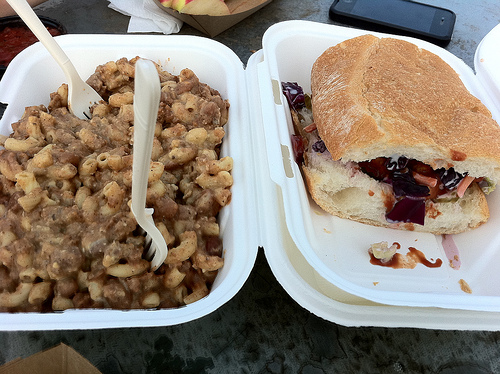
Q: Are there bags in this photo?
A: No, there are no bags.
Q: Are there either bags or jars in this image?
A: No, there are no bags or jars.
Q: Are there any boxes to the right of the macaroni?
A: Yes, there is a box to the right of the macaroni.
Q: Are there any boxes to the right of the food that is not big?
A: Yes, there is a box to the right of the macaroni.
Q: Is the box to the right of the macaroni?
A: Yes, the box is to the right of the macaroni.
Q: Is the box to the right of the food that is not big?
A: Yes, the box is to the right of the macaroni.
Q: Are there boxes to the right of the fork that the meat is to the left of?
A: Yes, there is a box to the right of the fork.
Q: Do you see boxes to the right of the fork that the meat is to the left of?
A: Yes, there is a box to the right of the fork.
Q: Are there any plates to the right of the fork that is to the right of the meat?
A: No, there is a box to the right of the fork.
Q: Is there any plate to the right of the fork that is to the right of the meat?
A: No, there is a box to the right of the fork.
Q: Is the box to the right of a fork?
A: Yes, the box is to the right of a fork.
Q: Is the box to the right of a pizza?
A: No, the box is to the right of a fork.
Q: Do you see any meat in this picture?
A: Yes, there is meat.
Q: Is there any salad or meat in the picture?
A: Yes, there is meat.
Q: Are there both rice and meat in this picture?
A: No, there is meat but no rice.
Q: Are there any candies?
A: No, there are no candies.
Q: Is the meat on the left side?
A: Yes, the meat is on the left of the image.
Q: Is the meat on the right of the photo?
A: No, the meat is on the left of the image.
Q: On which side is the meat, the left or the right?
A: The meat is on the left of the image.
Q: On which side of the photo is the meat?
A: The meat is on the left of the image.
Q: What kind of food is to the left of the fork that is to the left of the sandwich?
A: The food is meat.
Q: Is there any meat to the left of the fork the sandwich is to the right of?
A: Yes, there is meat to the left of the fork.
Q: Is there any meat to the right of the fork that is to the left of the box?
A: No, the meat is to the left of the fork.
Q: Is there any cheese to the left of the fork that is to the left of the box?
A: No, there is meat to the left of the fork.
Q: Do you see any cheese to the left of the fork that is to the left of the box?
A: No, there is meat to the left of the fork.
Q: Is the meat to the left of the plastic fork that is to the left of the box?
A: Yes, the meat is to the left of the fork.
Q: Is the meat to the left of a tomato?
A: No, the meat is to the left of the fork.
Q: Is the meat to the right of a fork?
A: No, the meat is to the left of a fork.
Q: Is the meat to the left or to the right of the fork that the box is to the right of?
A: The meat is to the left of the fork.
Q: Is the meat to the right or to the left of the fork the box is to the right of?
A: The meat is to the left of the fork.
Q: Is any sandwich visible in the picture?
A: Yes, there is a sandwich.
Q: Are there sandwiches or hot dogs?
A: Yes, there is a sandwich.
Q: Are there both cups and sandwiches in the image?
A: No, there is a sandwich but no cups.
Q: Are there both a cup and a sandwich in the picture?
A: No, there is a sandwich but no cups.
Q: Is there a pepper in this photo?
A: No, there are no peppers.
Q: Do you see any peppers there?
A: No, there are no peppers.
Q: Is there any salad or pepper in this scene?
A: No, there are no peppers or salad.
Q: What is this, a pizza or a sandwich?
A: This is a sandwich.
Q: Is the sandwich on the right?
A: Yes, the sandwich is on the right of the image.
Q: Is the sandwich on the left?
A: No, the sandwich is on the right of the image.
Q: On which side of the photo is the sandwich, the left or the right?
A: The sandwich is on the right of the image.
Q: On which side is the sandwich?
A: The sandwich is on the right of the image.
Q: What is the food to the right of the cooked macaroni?
A: The food is a sandwich.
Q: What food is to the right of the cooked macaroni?
A: The food is a sandwich.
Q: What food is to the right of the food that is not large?
A: The food is a sandwich.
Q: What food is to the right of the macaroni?
A: The food is a sandwich.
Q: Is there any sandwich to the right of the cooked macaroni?
A: Yes, there is a sandwich to the right of the macaroni.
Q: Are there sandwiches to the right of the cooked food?
A: Yes, there is a sandwich to the right of the macaroni.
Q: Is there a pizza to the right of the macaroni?
A: No, there is a sandwich to the right of the macaroni.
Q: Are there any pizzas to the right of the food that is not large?
A: No, there is a sandwich to the right of the macaroni.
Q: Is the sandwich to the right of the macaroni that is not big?
A: Yes, the sandwich is to the right of the macaroni.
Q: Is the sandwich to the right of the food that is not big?
A: Yes, the sandwich is to the right of the macaroni.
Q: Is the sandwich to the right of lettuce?
A: No, the sandwich is to the right of the macaroni.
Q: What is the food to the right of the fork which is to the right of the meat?
A: The food is a sandwich.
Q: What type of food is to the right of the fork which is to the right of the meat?
A: The food is a sandwich.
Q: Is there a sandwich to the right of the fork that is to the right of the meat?
A: Yes, there is a sandwich to the right of the fork.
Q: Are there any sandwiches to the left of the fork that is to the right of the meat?
A: No, the sandwich is to the right of the fork.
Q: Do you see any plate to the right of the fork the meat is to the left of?
A: No, there is a sandwich to the right of the fork.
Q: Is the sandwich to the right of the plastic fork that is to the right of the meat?
A: Yes, the sandwich is to the right of the fork.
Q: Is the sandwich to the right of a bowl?
A: No, the sandwich is to the right of the fork.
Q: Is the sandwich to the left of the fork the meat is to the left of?
A: No, the sandwich is to the right of the fork.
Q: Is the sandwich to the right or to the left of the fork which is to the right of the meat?
A: The sandwich is to the right of the fork.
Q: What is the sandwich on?
A: The sandwich is on the sauce.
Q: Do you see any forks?
A: Yes, there is a fork.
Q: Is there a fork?
A: Yes, there is a fork.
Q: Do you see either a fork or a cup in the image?
A: Yes, there is a fork.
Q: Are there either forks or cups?
A: Yes, there is a fork.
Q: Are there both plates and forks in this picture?
A: No, there is a fork but no plates.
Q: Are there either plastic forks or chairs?
A: Yes, there is a plastic fork.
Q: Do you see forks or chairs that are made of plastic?
A: Yes, the fork is made of plastic.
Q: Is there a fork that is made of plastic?
A: Yes, there is a fork that is made of plastic.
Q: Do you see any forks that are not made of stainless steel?
A: Yes, there is a fork that is made of plastic.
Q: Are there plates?
A: No, there are no plates.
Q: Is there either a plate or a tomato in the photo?
A: No, there are no plates or tomatoes.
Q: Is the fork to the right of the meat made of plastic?
A: Yes, the fork is made of plastic.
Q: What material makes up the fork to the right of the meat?
A: The fork is made of plastic.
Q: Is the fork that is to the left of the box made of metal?
A: No, the fork is made of plastic.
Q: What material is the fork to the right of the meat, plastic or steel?
A: The fork is made of plastic.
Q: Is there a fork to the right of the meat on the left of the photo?
A: Yes, there is a fork to the right of the meat.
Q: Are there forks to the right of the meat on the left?
A: Yes, there is a fork to the right of the meat.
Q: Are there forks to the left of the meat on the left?
A: No, the fork is to the right of the meat.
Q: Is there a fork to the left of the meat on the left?
A: No, the fork is to the right of the meat.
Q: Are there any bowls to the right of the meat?
A: No, there is a fork to the right of the meat.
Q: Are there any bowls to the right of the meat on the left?
A: No, there is a fork to the right of the meat.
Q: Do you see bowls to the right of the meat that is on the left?
A: No, there is a fork to the right of the meat.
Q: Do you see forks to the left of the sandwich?
A: Yes, there is a fork to the left of the sandwich.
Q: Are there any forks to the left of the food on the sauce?
A: Yes, there is a fork to the left of the sandwich.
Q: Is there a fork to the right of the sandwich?
A: No, the fork is to the left of the sandwich.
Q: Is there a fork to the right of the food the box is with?
A: No, the fork is to the left of the sandwich.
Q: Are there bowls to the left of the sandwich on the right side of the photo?
A: No, there is a fork to the left of the sandwich.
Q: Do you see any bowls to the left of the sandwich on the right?
A: No, there is a fork to the left of the sandwich.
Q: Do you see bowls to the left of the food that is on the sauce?
A: No, there is a fork to the left of the sandwich.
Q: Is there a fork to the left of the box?
A: Yes, there is a fork to the left of the box.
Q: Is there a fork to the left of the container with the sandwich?
A: Yes, there is a fork to the left of the box.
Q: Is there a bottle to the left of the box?
A: No, there is a fork to the left of the box.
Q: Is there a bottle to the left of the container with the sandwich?
A: No, there is a fork to the left of the box.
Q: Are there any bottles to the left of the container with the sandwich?
A: No, there is a fork to the left of the box.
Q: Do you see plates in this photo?
A: No, there are no plates.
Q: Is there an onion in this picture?
A: No, there are no onions.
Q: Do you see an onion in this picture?
A: No, there are no onions.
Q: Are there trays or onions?
A: No, there are no onions or trays.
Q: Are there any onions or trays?
A: No, there are no onions or trays.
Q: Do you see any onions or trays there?
A: No, there are no onions or trays.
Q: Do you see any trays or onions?
A: No, there are no onions or trays.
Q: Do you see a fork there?
A: Yes, there is a fork.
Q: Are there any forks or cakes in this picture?
A: Yes, there is a fork.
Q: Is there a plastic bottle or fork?
A: Yes, there is a plastic fork.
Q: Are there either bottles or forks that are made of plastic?
A: Yes, the fork is made of plastic.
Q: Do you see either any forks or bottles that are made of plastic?
A: Yes, the fork is made of plastic.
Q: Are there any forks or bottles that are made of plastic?
A: Yes, the fork is made of plastic.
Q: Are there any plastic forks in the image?
A: Yes, there is a fork that is made of plastic.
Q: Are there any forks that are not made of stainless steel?
A: Yes, there is a fork that is made of plastic.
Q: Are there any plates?
A: No, there are no plates.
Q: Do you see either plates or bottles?
A: No, there are no plates or bottles.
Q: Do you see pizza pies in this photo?
A: No, there are no pizza pies.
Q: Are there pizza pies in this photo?
A: No, there are no pizza pies.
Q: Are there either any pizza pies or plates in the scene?
A: No, there are no pizza pies or plates.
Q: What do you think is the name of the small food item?
A: The food item is macaroni.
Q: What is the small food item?
A: The food item is macaroni.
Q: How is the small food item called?
A: The food item is macaroni.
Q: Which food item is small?
A: The food item is macaroni.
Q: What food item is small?
A: The food item is macaroni.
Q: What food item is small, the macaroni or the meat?
A: The macaroni is small.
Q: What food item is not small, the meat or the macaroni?
A: The meat is not small.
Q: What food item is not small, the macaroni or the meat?
A: The meat is not small.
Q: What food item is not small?
A: The food item is meat.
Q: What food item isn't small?
A: The food item is meat.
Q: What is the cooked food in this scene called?
A: The food is macaroni.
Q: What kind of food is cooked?
A: The food is macaroni.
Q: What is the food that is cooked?
A: The food is macaroni.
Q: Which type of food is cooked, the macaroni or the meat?
A: The macaroni is cooked.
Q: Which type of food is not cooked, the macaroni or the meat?
A: The meat is not cooked.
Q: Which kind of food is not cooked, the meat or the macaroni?
A: The meat is not cooked.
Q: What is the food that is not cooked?
A: The food is meat.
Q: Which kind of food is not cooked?
A: The food is meat.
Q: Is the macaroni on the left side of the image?
A: Yes, the macaroni is on the left of the image.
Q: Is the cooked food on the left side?
A: Yes, the macaroni is on the left of the image.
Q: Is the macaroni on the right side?
A: No, the macaroni is on the left of the image.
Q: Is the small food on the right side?
A: No, the macaroni is on the left of the image.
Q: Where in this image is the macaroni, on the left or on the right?
A: The macaroni is on the left of the image.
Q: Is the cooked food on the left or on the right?
A: The macaroni is on the left of the image.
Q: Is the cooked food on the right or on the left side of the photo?
A: The macaroni is on the left of the image.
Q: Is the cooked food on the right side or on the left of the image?
A: The macaroni is on the left of the image.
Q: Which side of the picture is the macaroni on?
A: The macaroni is on the left of the image.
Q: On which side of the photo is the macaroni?
A: The macaroni is on the left of the image.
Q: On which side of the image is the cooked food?
A: The macaroni is on the left of the image.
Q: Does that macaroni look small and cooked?
A: Yes, the macaroni is small and cooked.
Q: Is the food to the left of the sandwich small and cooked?
A: Yes, the macaroni is small and cooked.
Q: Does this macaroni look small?
A: Yes, the macaroni is small.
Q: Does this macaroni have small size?
A: Yes, the macaroni is small.